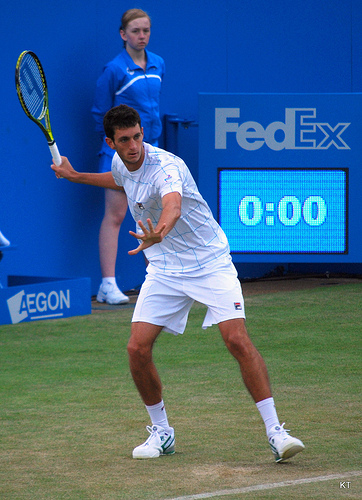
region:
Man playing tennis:
[14, 49, 305, 462]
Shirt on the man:
[110, 141, 230, 272]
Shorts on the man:
[130, 262, 246, 333]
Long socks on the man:
[143, 396, 280, 434]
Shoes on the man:
[131, 423, 305, 462]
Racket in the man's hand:
[14, 48, 64, 178]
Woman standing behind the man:
[90, 7, 175, 304]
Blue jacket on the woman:
[89, 49, 163, 157]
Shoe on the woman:
[95, 280, 128, 303]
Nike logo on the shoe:
[97, 287, 107, 295]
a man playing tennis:
[21, 22, 351, 355]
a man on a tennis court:
[14, 58, 333, 438]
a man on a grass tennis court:
[40, 43, 344, 430]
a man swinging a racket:
[17, 32, 235, 236]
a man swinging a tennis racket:
[4, 50, 218, 237]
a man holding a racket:
[9, 48, 273, 285]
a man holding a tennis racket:
[9, 29, 303, 328]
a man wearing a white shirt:
[28, 45, 323, 347]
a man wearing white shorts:
[56, 98, 359, 419]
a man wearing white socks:
[93, 118, 323, 491]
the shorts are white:
[113, 261, 245, 328]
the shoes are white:
[125, 372, 304, 459]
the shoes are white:
[102, 432, 330, 487]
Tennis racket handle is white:
[49, 141, 62, 168]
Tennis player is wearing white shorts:
[50, 102, 307, 462]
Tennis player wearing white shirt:
[49, 103, 307, 465]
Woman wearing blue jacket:
[93, 5, 167, 299]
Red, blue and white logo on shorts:
[234, 299, 243, 312]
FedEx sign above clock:
[210, 104, 354, 156]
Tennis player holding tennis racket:
[46, 105, 307, 463]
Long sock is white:
[144, 398, 168, 431]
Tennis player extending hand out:
[48, 103, 306, 463]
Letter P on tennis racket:
[18, 61, 43, 101]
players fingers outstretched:
[117, 213, 185, 259]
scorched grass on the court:
[184, 454, 257, 476]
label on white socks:
[158, 403, 171, 410]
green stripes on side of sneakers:
[158, 433, 175, 449]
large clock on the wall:
[210, 165, 360, 257]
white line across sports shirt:
[98, 67, 175, 91]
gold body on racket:
[10, 43, 60, 145]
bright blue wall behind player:
[212, 25, 303, 76]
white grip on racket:
[42, 139, 73, 164]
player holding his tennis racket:
[104, 109, 295, 466]